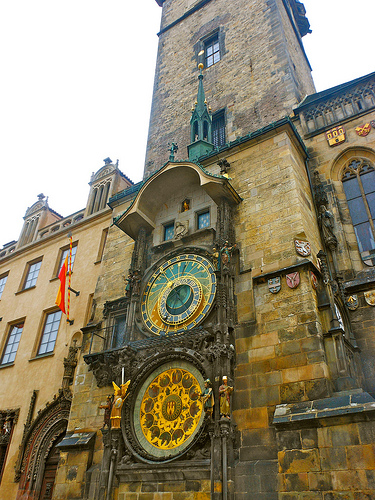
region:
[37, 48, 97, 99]
this is the sky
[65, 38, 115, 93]
the sky is bright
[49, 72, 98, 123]
the sky has clouds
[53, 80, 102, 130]
the clouds are white in color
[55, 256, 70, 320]
this is a flag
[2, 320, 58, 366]
these are some windows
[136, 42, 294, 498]
this is a building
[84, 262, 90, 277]
the wall is brown in color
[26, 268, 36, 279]
the window is closed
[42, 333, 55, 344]
the window is made of glass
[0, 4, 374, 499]
Big size building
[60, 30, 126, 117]
Sky with clouds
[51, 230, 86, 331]
Flag and metal pole attached to the wall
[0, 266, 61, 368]
Glass windows in the building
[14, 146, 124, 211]
Top of the building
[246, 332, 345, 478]
Building made up of stones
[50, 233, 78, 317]
Orange and yellow color flag hoisting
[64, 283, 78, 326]
Orange and yellow color pole attached with clamps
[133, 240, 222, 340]
Roman letter clock in the building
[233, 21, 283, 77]
Bricks of the building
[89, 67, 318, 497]
this is a church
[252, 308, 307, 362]
this is the wall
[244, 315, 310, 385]
the wall is old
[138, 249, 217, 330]
this is the clock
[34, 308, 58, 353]
this is the window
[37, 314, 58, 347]
the window is closed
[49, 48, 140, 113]
this is the sky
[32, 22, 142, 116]
the sky is white in color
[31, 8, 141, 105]
the sky is clear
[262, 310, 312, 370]
the wall is rusty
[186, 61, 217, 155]
a dark green steeple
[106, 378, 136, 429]
a gold angel statue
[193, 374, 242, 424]
a pair of small statues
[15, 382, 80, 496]
a large, decorative archway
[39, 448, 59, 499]
a heavy wood door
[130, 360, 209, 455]
a round gold piece of decor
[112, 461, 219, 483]
a small brick ledge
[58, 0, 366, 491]
an old stone building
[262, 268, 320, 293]
a row of shields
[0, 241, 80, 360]
a few rectangular windows